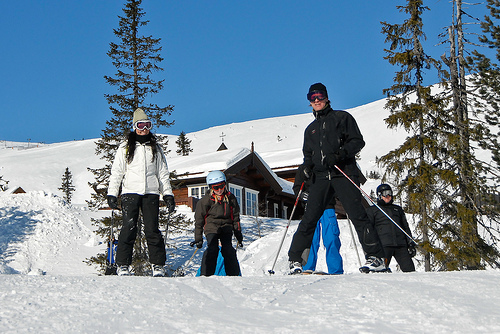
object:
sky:
[3, 0, 500, 142]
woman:
[98, 104, 179, 278]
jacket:
[106, 137, 178, 197]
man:
[283, 82, 393, 275]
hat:
[306, 82, 329, 97]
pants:
[287, 174, 386, 262]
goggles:
[132, 120, 153, 131]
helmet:
[132, 107, 151, 125]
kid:
[191, 170, 250, 278]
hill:
[0, 70, 500, 290]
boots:
[115, 262, 133, 277]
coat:
[288, 106, 367, 185]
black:
[314, 127, 347, 183]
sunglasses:
[308, 93, 328, 102]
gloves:
[321, 151, 339, 170]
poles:
[266, 181, 307, 276]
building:
[97, 144, 303, 217]